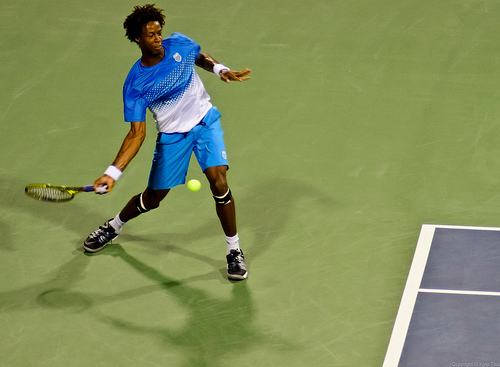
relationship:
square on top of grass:
[389, 227, 499, 366] [2, 3, 499, 365]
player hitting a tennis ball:
[25, 2, 252, 279] [185, 178, 198, 189]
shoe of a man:
[226, 247, 248, 279] [82, 3, 252, 279]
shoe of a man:
[83, 217, 121, 252] [82, 3, 252, 279]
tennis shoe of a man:
[90, 219, 115, 254] [82, 3, 252, 279]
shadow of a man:
[80, 243, 284, 365] [82, 3, 252, 279]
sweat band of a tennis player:
[103, 162, 122, 181] [84, 3, 248, 279]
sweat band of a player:
[103, 162, 122, 181] [71, 6, 296, 287]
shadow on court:
[80, 243, 284, 365] [322, 37, 495, 252]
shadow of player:
[80, 243, 284, 365] [25, 2, 252, 279]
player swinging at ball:
[25, 2, 252, 279] [181, 175, 202, 191]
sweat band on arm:
[103, 162, 122, 181] [92, 112, 144, 190]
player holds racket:
[25, 2, 252, 279] [12, 172, 95, 214]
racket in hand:
[12, 172, 95, 214] [90, 170, 118, 197]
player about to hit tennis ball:
[25, 2, 252, 279] [185, 178, 198, 189]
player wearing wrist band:
[25, 2, 252, 279] [211, 64, 226, 76]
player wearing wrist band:
[25, 2, 252, 279] [105, 161, 122, 180]